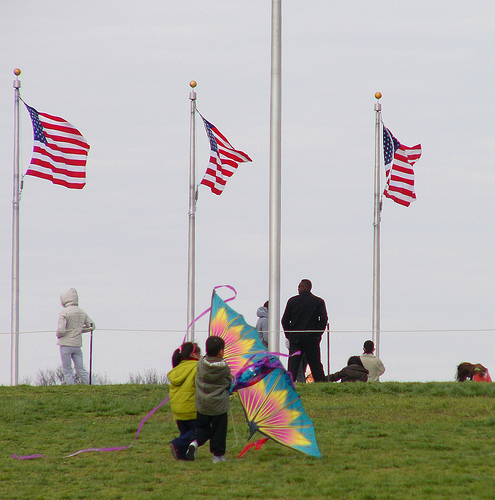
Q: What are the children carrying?
A: A kite.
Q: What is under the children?
A: Grass.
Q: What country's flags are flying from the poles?
A: United States.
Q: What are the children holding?
A: A colorful kite.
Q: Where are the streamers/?
A: On the kite.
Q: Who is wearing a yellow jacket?
A: The little girl on the left.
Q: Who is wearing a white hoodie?
A: The person standing by the flagpole on the left.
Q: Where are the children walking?
A: Toward the flags.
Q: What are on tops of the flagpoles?
A: Gold balls.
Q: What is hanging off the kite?
A: Stramers.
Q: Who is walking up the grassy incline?
A: Two children.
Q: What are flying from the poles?
A: US flags.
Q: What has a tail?
A: Kite.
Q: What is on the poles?
A: Flags.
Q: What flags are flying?
A: American.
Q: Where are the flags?
A: On poles.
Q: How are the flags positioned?
A: Full Mast.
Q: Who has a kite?
A: Children.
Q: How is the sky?
A: Cloudy.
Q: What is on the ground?
A: Grass.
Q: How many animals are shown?
A: None.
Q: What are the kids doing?
A: Holding a kite.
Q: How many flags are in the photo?
A: Three.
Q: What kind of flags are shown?
A: American.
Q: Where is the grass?
A: Under the people.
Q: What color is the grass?
A: Green.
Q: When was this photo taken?
A: Daytime.